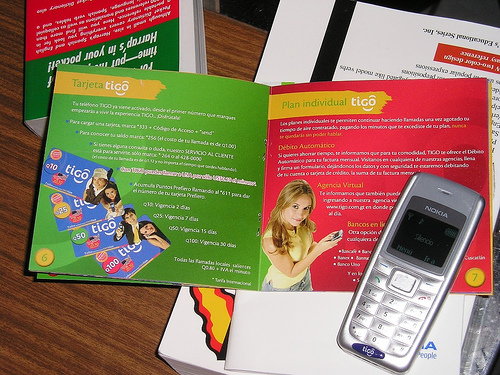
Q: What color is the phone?
A: Gray.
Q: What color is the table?
A: Brown.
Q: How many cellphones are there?
A: One.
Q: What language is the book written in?
A: Spanish.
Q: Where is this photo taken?
A: At a table.